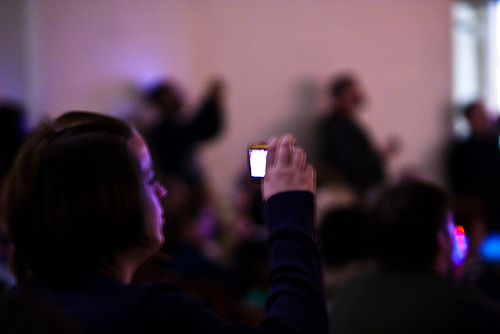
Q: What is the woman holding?
A: A camera.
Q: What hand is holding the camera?
A: The right hand.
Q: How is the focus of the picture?
A: Off focus.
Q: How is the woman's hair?
A: Pulled back.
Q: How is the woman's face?
A: Illuminated with a purple tint.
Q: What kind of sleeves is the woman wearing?
A: Long sleeves.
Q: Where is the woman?
A: In a large room.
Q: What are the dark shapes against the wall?
A: Other audience members.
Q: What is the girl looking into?
A: Camera screen.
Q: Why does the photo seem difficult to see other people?
A: Photo is blurry.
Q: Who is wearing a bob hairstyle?
A: The woman in front.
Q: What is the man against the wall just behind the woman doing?
A: Holding up a phone to take a picture.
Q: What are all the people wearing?
A: Dark clothes.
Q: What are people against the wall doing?
A: Watching something at the front of the room.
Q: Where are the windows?
A: On the right.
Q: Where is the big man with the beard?
A: Leaning against the wall.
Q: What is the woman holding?
A: A phone.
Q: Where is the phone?
A: In a hand.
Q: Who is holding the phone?
A: A woman.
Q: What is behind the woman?
A: Blurry people.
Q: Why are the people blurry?
A: They are out of focus.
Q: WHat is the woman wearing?
A: A long sleeve shirt.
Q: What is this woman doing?
A: Filming.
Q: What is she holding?
A: Camera.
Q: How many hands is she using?
A: One.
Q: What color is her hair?
A: Brown.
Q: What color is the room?
A: White.